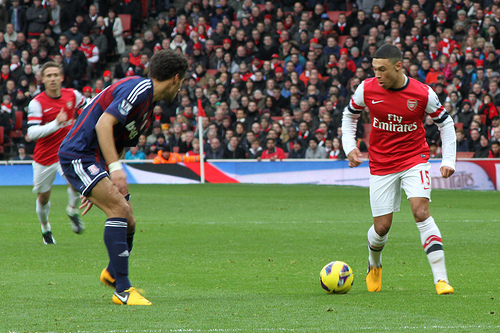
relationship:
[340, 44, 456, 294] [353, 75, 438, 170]
guy in a red jersey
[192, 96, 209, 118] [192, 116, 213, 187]
red flag on a white pole